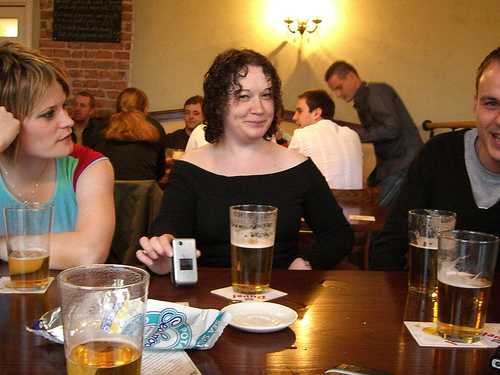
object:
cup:
[227, 205, 280, 294]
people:
[124, 49, 353, 272]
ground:
[450, 174, 454, 178]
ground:
[421, 138, 448, 193]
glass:
[435, 231, 500, 344]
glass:
[60, 265, 149, 375]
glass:
[3, 201, 55, 291]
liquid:
[436, 274, 489, 339]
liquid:
[407, 241, 437, 297]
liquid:
[230, 241, 273, 294]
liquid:
[62, 338, 146, 373]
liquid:
[8, 251, 50, 291]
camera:
[179, 241, 183, 246]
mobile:
[170, 237, 199, 288]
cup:
[58, 263, 149, 375]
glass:
[406, 207, 459, 292]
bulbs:
[286, 13, 325, 40]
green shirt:
[0, 143, 111, 238]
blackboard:
[49, 0, 122, 45]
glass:
[225, 203, 279, 295]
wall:
[2, 0, 499, 140]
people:
[325, 59, 427, 206]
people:
[354, 45, 498, 272]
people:
[281, 90, 366, 187]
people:
[156, 94, 208, 150]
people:
[81, 87, 164, 183]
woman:
[0, 37, 117, 268]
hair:
[2, 39, 41, 94]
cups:
[436, 230, 500, 338]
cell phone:
[172, 236, 201, 289]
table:
[0, 269, 500, 375]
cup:
[7, 200, 52, 290]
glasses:
[406, 208, 462, 295]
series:
[403, 204, 499, 344]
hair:
[202, 69, 238, 100]